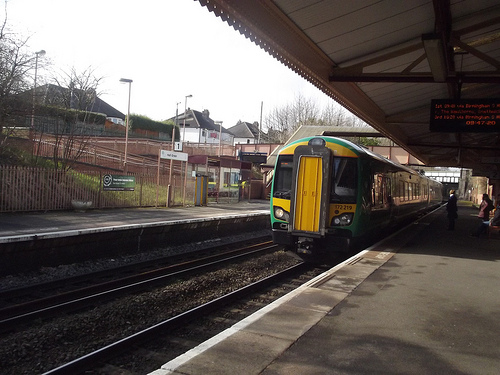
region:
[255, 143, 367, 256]
the back of a moving train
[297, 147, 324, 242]
the door of a train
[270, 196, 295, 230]
the head light of a train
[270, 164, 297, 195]
the left window of a train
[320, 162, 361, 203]
the right window of a train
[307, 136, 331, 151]
the top light of a train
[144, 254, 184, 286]
the empty train tracks at the station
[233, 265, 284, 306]
the occupied train tracks at the station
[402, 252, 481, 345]
the cement platform of the train station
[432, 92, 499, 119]
an electric information sign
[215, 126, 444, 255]
This is a train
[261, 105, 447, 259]
the train is at the station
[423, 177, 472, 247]
this is a person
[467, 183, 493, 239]
this is a person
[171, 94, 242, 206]
this is a building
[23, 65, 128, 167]
this is a building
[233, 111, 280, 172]
this is a building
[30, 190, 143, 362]
this is a railway track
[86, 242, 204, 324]
this is a railway track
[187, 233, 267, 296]
this is a railway track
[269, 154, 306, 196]
window of a train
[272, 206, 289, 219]
light of a train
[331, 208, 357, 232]
head light of a train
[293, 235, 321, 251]
mount of a train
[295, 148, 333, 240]
door of a train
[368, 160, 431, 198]
windows of a train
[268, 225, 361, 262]
bumper of a train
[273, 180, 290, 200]
wipers of a train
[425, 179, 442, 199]
window of a train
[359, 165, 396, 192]
window of a train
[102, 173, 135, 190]
Green banner on a fence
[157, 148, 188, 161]
White posting on a pole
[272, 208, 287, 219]
Headlight on a train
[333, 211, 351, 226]
Left headlight on a train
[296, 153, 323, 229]
Yellow door on train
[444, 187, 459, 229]
Man standing by a train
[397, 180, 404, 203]
Window on a train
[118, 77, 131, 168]
Light pole outside by a train station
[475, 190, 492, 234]
Person waiting by a train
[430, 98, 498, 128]
A display near a train